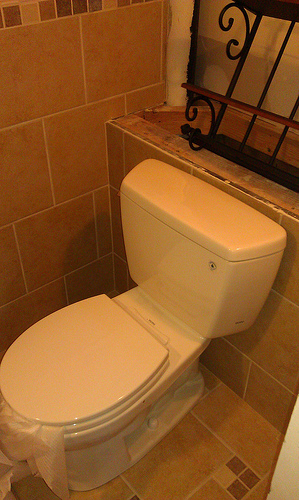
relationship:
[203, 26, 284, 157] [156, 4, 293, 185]
rack on wall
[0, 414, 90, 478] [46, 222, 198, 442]
paper for toilet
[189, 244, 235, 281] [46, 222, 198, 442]
logo on toilet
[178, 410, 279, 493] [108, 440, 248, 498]
tiles on floor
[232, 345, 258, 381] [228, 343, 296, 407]
lines of grout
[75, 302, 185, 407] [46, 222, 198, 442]
lid of toilet